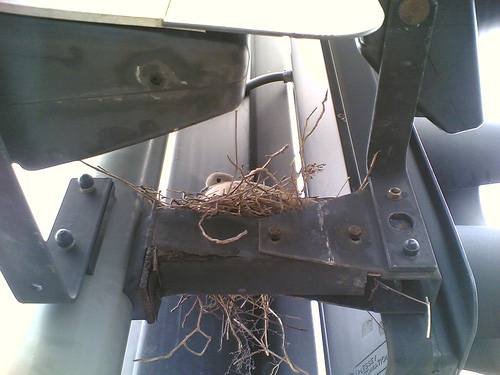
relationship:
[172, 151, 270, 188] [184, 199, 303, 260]
bird in nest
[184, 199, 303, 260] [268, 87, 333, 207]
nest of twig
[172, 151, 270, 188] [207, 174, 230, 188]
bird has eye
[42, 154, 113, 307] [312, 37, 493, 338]
bolts in bridge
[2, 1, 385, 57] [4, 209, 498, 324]
projection over structure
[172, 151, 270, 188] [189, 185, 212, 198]
bird has beak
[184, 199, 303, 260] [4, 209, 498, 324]
nest on structure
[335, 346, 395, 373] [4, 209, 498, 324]
writing on structure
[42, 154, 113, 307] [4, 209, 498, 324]
bolts in structure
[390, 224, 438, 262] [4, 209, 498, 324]
bolt in structure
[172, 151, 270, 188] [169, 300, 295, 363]
bird has nest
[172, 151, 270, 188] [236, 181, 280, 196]
bird has feathers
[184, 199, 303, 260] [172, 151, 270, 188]
nest for bird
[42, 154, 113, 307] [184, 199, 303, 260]
bolts by nest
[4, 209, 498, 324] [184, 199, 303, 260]
structure with nest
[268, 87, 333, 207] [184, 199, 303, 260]
twig on nest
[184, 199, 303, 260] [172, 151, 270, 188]
nest of bird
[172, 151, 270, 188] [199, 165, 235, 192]
bird has head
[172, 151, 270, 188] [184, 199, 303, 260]
bird has nest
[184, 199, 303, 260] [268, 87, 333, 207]
nest has twig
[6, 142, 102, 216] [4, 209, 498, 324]
sunlight by structure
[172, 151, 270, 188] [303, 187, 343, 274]
bird has poop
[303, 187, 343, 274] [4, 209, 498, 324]
poop on structure